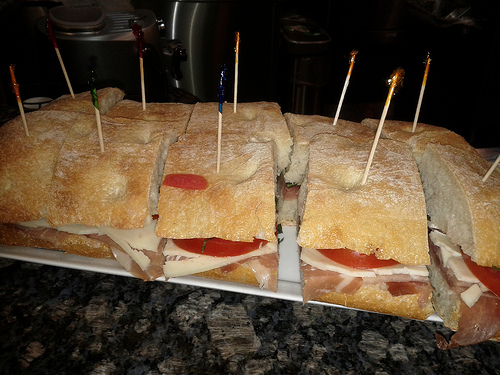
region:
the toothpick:
[153, 84, 421, 291]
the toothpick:
[161, 78, 321, 245]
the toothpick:
[176, 71, 273, 214]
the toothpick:
[182, 69, 249, 168]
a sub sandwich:
[3, 70, 496, 350]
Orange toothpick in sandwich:
[0, 53, 36, 156]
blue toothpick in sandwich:
[196, 60, 232, 189]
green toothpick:
[66, 52, 115, 171]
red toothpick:
[106, 17, 163, 124]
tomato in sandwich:
[164, 226, 286, 266]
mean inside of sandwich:
[433, 287, 498, 352]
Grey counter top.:
[3, 323, 441, 373]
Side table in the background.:
[270, 10, 331, 120]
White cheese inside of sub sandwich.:
[434, 216, 481, 306]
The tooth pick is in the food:
[195, 64, 292, 265]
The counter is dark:
[36, 277, 193, 373]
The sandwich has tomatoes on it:
[295, 204, 451, 360]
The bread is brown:
[44, 122, 181, 265]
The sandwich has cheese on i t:
[156, 237, 263, 329]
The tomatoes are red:
[330, 241, 442, 293]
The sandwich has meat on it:
[451, 275, 498, 351]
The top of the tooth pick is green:
[72, 57, 120, 132]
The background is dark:
[101, 4, 338, 134]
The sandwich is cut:
[169, 203, 448, 352]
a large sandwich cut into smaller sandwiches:
[2, 27, 497, 339]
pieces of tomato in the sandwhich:
[168, 230, 498, 298]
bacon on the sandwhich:
[296, 264, 498, 348]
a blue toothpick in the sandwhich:
[211, 66, 228, 176]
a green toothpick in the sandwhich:
[89, 59, 107, 153]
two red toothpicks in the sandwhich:
[36, 5, 157, 112]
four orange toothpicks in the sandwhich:
[230, 27, 442, 192]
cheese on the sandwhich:
[16, 210, 495, 305]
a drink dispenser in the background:
[25, 0, 198, 97]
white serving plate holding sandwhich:
[0, 203, 455, 325]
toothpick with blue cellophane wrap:
[205, 62, 240, 172]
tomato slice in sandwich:
[325, 237, 402, 274]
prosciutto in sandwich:
[302, 262, 421, 303]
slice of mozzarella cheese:
[301, 245, 430, 282]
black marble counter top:
[30, 290, 366, 372]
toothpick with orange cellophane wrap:
[355, 68, 405, 192]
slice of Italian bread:
[158, 128, 281, 247]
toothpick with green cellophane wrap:
[81, 72, 113, 158]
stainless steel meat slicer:
[44, 5, 199, 100]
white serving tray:
[10, 212, 497, 339]